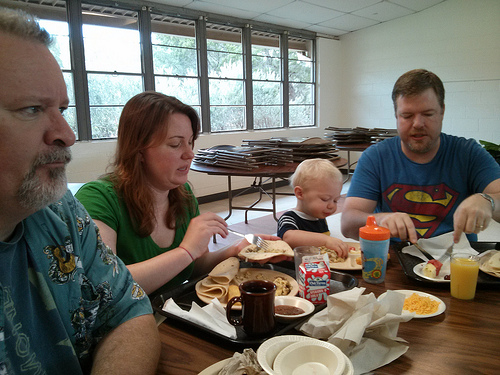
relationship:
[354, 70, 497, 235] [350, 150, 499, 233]
man wearing superman shirt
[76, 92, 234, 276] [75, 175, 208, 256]
woman wearing green shirt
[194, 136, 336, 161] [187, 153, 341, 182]
chairs on top of table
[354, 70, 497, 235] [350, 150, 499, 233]
man wearing a blue shirt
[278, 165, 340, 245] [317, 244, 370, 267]
boy picking up food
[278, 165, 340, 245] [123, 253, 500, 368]
young child sitting at table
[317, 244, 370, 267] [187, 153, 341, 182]
food on table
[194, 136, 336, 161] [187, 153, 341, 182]
chairs stacked on top of table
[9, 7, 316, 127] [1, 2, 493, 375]
windows in room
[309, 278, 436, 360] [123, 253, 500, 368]
napkins on table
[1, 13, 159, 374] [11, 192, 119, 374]
man in blue shirt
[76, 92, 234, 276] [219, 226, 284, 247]
woman holding fork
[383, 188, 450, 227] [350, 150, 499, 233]
logo on shirt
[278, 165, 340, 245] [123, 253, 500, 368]
boy sitting at table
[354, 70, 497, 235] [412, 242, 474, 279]
man cutting food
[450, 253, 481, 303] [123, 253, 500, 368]
orange juice on table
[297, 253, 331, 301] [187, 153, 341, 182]
carton on table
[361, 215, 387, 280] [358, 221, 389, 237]
sippy cup with orange top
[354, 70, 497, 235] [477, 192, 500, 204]
man wearing a watch